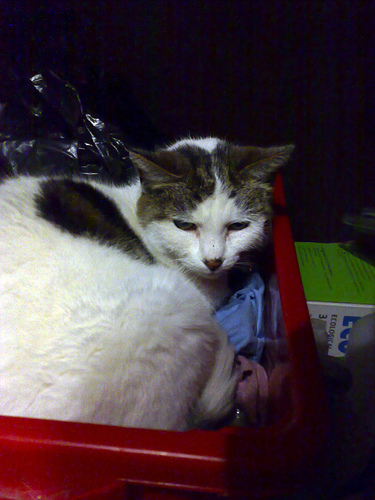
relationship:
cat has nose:
[0, 134, 297, 439] [205, 254, 222, 271]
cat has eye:
[0, 134, 297, 439] [174, 214, 204, 239]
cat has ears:
[0, 134, 297, 439] [118, 142, 302, 181]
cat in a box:
[0, 134, 297, 439] [3, 126, 328, 498]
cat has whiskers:
[0, 134, 297, 439] [150, 239, 259, 281]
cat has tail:
[0, 134, 297, 439] [3, 331, 264, 429]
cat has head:
[0, 134, 297, 439] [114, 136, 298, 280]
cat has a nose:
[0, 134, 297, 439] [205, 254, 222, 271]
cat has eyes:
[0, 134, 297, 439] [176, 214, 259, 236]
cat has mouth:
[0, 134, 297, 439] [187, 246, 235, 279]